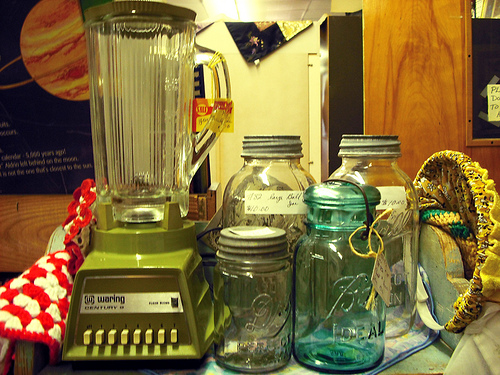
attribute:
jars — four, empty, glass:
[208, 142, 438, 372]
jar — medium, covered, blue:
[287, 167, 396, 374]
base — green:
[67, 169, 230, 360]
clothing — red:
[1, 182, 120, 355]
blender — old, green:
[36, 1, 241, 373]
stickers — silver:
[250, 179, 309, 221]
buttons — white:
[80, 326, 179, 352]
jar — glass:
[218, 213, 292, 366]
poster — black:
[3, 2, 212, 188]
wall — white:
[213, 32, 301, 168]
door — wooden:
[356, 3, 493, 193]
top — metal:
[241, 134, 311, 160]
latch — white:
[242, 126, 293, 166]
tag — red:
[193, 92, 239, 138]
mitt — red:
[2, 100, 108, 371]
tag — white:
[245, 187, 308, 220]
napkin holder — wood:
[424, 122, 494, 357]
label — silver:
[79, 291, 178, 314]